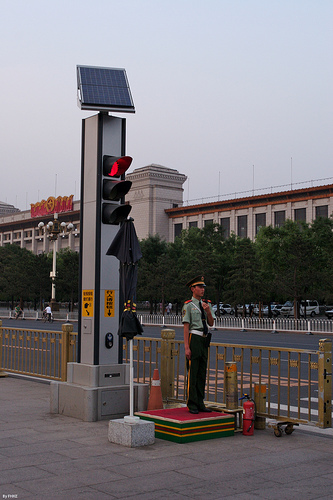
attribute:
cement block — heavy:
[105, 412, 156, 447]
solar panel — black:
[74, 64, 134, 112]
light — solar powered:
[77, 116, 170, 366]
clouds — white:
[163, 26, 311, 150]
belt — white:
[184, 328, 209, 338]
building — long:
[2, 163, 330, 257]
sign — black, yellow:
[102, 286, 117, 317]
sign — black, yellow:
[79, 288, 95, 318]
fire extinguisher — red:
[239, 393, 257, 436]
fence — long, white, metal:
[15, 304, 328, 339]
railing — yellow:
[2, 324, 332, 429]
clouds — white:
[201, 82, 269, 105]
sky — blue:
[0, 1, 333, 212]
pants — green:
[184, 330, 216, 414]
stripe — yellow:
[183, 329, 197, 403]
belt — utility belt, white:
[186, 324, 209, 340]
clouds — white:
[0, 0, 332, 210]